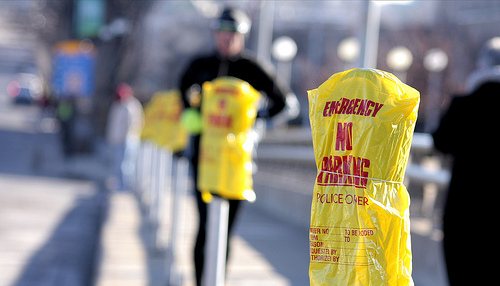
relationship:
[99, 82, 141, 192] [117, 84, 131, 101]
man wearing cap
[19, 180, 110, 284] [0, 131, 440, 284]
shadow on ground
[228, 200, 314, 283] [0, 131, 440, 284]
shadow on ground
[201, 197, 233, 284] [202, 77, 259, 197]
metal pole on parking meter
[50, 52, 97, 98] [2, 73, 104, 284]
blue sign on road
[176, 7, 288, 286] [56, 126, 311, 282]
man jogging down sidewalk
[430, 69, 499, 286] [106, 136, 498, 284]
man walking up sidewalk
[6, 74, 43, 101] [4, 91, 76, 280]
car driving down road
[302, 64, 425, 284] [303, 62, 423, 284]
yellow plastic over parking meter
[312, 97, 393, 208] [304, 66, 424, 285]
writing on plastic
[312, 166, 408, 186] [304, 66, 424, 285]
string around plastic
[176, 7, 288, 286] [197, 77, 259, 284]
man next to parking meters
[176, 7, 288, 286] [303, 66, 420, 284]
man next to parking meters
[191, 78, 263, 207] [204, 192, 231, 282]
bag on pole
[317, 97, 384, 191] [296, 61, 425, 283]
words on bag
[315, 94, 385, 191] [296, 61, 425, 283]
word on bag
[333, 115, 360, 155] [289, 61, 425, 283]
no on sign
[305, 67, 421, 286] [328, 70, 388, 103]
bag over parking meter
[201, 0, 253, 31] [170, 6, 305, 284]
hat on man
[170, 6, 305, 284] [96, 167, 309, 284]
man on sidewalk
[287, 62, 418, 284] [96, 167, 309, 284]
parking meter on sidewalk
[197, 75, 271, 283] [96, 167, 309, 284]
parking meter on sidewalk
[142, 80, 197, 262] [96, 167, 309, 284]
parking meter on sidewalk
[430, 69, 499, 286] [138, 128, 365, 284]
man walking down sidewalk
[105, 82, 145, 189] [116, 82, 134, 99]
man wearing cap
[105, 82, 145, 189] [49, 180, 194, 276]
man walking down sidewalk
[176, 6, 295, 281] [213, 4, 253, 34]
man wearing hat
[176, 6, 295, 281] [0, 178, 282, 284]
man jogging on sidewalk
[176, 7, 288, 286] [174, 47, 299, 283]
man in uniform